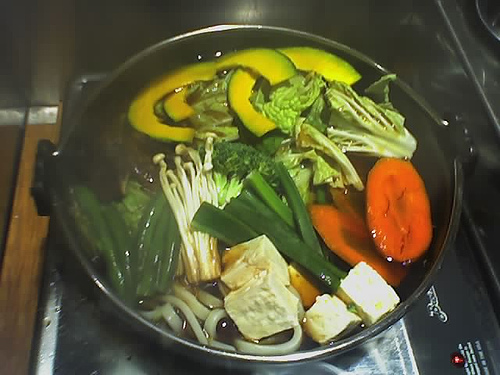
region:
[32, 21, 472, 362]
Pot of boiled vegetables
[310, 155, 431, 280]
Boiled chopped carrots in pot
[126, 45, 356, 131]
Sliced avocados boiled in a pot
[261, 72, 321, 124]
Boiled cabbage in a pot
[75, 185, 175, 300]
Sliced green beans boiled in a pot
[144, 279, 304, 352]
Boiled noodles in a pot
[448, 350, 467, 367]
Light to indicate that the stove is hot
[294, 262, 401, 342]
Sliced plantains boiled in a pot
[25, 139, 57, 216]
Left handle bar of pot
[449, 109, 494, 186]
Right handle bar of pot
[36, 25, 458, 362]
Metal pan with vegetables.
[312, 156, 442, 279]
Sweet potatoes in pan.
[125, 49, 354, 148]
Avacados in pan.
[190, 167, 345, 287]
Green peppers in pan.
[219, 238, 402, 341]
Tofu in pan on stove.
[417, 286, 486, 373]
Brand of stove top.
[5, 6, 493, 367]
Stove top with pan on stove.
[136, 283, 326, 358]
Onion in pan on stove.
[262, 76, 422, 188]
Broccoli in pan on stove.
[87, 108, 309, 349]
Liquid in pan on stove.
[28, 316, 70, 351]
white edge of stove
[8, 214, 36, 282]
brown wood section of stove top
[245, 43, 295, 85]
juicy piece of avocado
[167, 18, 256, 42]
shiny edge of black skillet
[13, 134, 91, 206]
handle on black skillet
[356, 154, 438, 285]
small cut piece of carrot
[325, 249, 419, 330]
small piece of white tofu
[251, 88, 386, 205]
crisp lettuce leaves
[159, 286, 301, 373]
noodles in brown broth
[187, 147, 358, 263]
rough edge of green scallions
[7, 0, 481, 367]
Black pan with soup.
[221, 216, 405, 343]
Tofu in the soup.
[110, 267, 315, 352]
Noodles in the soup.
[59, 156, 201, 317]
Green beans in the soup.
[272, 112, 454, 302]
Three pieces of carrots.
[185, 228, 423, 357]
Four pieces of tofu.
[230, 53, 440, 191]
Lettuce in the soup.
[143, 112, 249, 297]
Bean sprouts in the soup.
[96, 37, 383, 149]
Pieces of squash.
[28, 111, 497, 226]
Two handles on the pot.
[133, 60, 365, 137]
The slices of avocado in the pot.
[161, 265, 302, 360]
The slices of onions in the pot.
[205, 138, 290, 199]
The pieces of broccoli in the pot.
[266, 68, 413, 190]
The pieces of lettuce in the pot.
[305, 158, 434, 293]
The pieces of sweet potato in the pot.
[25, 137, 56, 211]
The black handle of the pot on the left.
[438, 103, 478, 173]
The pot handle on the right.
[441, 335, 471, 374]
The little red light on the right.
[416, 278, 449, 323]
The black and white brand name of the electrical stove.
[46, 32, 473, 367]
The pot all of the vegetables and food items are in.